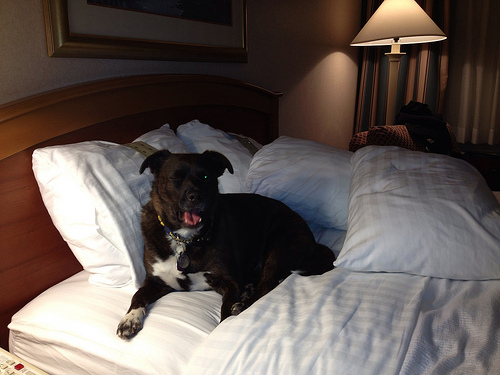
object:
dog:
[114, 149, 337, 341]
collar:
[152, 211, 219, 243]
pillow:
[31, 124, 194, 291]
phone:
[0, 346, 48, 373]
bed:
[8, 117, 499, 373]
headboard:
[0, 70, 284, 353]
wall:
[1, 1, 359, 149]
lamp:
[350, 1, 447, 124]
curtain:
[351, 1, 447, 132]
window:
[355, 1, 498, 143]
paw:
[115, 306, 147, 340]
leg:
[113, 278, 178, 341]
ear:
[203, 149, 234, 177]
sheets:
[8, 224, 346, 373]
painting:
[43, 1, 251, 64]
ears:
[139, 149, 172, 177]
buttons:
[2, 361, 27, 374]